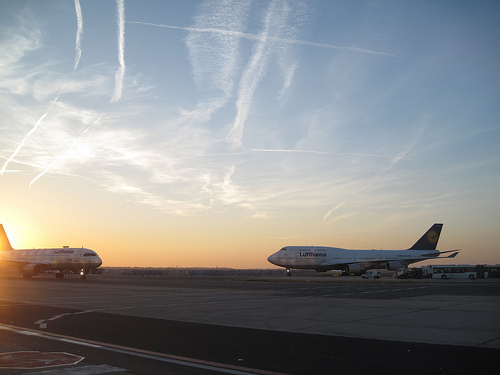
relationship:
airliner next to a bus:
[267, 221, 462, 277] [425, 259, 476, 279]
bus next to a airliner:
[426, 260, 487, 280] [267, 221, 462, 277]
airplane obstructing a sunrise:
[2, 222, 102, 277] [3, 196, 37, 250]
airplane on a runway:
[0, 222, 102, 279] [8, 281, 498, 366]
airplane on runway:
[0, 222, 102, 279] [8, 281, 498, 366]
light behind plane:
[9, 225, 51, 250] [0, 220, 107, 288]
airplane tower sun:
[2, 222, 102, 277] [0, 175, 65, 262]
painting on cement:
[0, 346, 85, 371] [2, 299, 478, 372]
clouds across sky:
[48, 54, 283, 222] [3, 12, 499, 260]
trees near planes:
[102, 261, 280, 283] [264, 217, 464, 287]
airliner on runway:
[267, 221, 460, 276] [95, 264, 467, 373]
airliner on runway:
[267, 221, 460, 276] [10, 282, 481, 351]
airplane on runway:
[0, 222, 102, 279] [10, 282, 481, 351]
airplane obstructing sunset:
[2, 222, 102, 277] [43, 198, 192, 341]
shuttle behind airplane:
[399, 266, 481, 281] [267, 220, 462, 275]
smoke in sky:
[1, 0, 424, 229] [3, 12, 499, 260]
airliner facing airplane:
[267, 221, 460, 276] [1, 218, 101, 286]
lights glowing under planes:
[47, 266, 299, 302] [7, 179, 468, 323]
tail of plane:
[2, 220, 12, 253] [0, 232, 105, 284]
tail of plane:
[409, 220, 444, 251] [266, 202, 470, 295]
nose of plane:
[82, 252, 106, 272] [21, 217, 150, 296]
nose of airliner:
[263, 249, 283, 263] [267, 221, 460, 276]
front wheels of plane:
[76, 266, 85, 277] [245, 215, 499, 295]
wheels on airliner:
[291, 259, 392, 301] [267, 221, 460, 276]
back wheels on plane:
[18, 270, 34, 277] [0, 220, 107, 288]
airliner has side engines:
[267, 221, 460, 276] [345, 261, 407, 274]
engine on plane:
[19, 263, 41, 275] [0, 222, 105, 274]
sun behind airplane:
[1, 212, 28, 257] [1, 217, 116, 282]